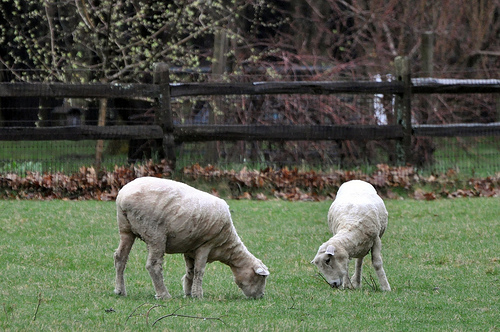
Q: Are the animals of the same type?
A: Yes, all the animals are sheep.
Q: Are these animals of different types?
A: No, all the animals are sheep.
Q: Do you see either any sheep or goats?
A: Yes, there is a sheep.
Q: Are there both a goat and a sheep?
A: No, there is a sheep but no goats.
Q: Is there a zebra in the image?
A: No, there are no zebras.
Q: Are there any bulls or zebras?
A: No, there are no zebras or bulls.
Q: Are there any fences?
A: Yes, there is a fence.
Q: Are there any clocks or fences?
A: Yes, there is a fence.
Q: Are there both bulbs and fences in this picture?
A: No, there is a fence but no light bulbs.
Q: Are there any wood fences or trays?
A: Yes, there is a wood fence.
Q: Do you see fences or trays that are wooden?
A: Yes, the fence is wooden.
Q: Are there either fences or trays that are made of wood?
A: Yes, the fence is made of wood.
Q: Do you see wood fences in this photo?
A: Yes, there is a wood fence.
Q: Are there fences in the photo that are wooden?
A: Yes, there is a fence that is wooden.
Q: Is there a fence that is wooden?
A: Yes, there is a fence that is wooden.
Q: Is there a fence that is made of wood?
A: Yes, there is a fence that is made of wood.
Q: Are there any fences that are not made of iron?
A: Yes, there is a fence that is made of wood.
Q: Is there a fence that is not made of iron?
A: Yes, there is a fence that is made of wood.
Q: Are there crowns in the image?
A: No, there are no crowns.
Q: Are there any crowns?
A: No, there are no crowns.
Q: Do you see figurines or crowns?
A: No, there are no crowns or figurines.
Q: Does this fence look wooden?
A: Yes, the fence is wooden.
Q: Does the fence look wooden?
A: Yes, the fence is wooden.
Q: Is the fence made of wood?
A: Yes, the fence is made of wood.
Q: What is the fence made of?
A: The fence is made of wood.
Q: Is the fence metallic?
A: No, the fence is wooden.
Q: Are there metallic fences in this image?
A: No, there is a fence but it is wooden.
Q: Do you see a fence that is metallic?
A: No, there is a fence but it is wooden.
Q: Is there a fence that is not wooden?
A: No, there is a fence but it is wooden.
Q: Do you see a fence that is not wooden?
A: No, there is a fence but it is wooden.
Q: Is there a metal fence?
A: No, there is a fence but it is made of wood.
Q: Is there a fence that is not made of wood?
A: No, there is a fence but it is made of wood.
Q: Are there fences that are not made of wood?
A: No, there is a fence but it is made of wood.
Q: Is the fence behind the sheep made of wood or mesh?
A: The fence is made of wood.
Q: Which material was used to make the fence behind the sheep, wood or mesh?
A: The fence is made of wood.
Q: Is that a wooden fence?
A: Yes, that is a wooden fence.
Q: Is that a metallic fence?
A: No, that is a wooden fence.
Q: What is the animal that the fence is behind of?
A: The animal is a sheep.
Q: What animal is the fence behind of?
A: The fence is behind the sheep.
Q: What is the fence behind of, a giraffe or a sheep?
A: The fence is behind a sheep.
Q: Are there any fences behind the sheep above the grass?
A: Yes, there is a fence behind the sheep.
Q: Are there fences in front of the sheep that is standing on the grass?
A: No, the fence is behind the sheep.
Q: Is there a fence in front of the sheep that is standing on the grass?
A: No, the fence is behind the sheep.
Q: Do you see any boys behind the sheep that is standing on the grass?
A: No, there is a fence behind the sheep.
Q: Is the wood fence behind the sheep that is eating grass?
A: Yes, the fence is behind the sheep.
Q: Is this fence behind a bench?
A: No, the fence is behind the sheep.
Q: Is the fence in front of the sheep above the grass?
A: No, the fence is behind the sheep.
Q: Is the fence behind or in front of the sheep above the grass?
A: The fence is behind the sheep.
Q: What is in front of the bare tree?
A: The fence is in front of the tree.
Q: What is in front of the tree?
A: The fence is in front of the tree.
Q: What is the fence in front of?
A: The fence is in front of the tree.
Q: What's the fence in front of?
A: The fence is in front of the tree.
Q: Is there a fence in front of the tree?
A: Yes, there is a fence in front of the tree.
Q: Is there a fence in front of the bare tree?
A: Yes, there is a fence in front of the tree.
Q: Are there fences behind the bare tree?
A: No, the fence is in front of the tree.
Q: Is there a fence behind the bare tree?
A: No, the fence is in front of the tree.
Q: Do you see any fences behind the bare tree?
A: No, the fence is in front of the tree.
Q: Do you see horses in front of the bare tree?
A: No, there is a fence in front of the tree.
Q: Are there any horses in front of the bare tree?
A: No, there is a fence in front of the tree.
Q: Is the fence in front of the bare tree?
A: Yes, the fence is in front of the tree.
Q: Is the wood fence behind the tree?
A: No, the fence is in front of the tree.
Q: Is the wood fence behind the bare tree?
A: No, the fence is in front of the tree.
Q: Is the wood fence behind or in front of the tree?
A: The fence is in front of the tree.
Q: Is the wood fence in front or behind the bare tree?
A: The fence is in front of the tree.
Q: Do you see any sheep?
A: Yes, there is a sheep.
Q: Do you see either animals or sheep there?
A: Yes, there is a sheep.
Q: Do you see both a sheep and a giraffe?
A: No, there is a sheep but no giraffes.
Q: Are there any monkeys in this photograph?
A: No, there are no monkeys.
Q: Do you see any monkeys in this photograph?
A: No, there are no monkeys.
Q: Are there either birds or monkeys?
A: No, there are no monkeys or birds.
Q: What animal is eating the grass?
A: The sheep is eating the grass.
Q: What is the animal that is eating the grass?
A: The animal is a sheep.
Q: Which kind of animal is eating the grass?
A: The animal is a sheep.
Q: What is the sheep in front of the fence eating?
A: The sheep is eating grass.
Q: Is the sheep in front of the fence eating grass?
A: Yes, the sheep is eating grass.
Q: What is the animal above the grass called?
A: The animal is a sheep.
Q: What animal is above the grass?
A: The animal is a sheep.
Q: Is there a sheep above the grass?
A: Yes, there is a sheep above the grass.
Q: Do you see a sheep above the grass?
A: Yes, there is a sheep above the grass.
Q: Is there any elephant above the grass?
A: No, there is a sheep above the grass.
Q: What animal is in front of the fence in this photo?
A: The sheep is in front of the fence.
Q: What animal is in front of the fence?
A: The sheep is in front of the fence.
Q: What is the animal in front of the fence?
A: The animal is a sheep.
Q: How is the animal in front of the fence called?
A: The animal is a sheep.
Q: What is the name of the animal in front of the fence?
A: The animal is a sheep.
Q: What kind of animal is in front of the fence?
A: The animal is a sheep.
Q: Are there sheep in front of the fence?
A: Yes, there is a sheep in front of the fence.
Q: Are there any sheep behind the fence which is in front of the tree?
A: No, the sheep is in front of the fence.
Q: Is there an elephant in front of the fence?
A: No, there is a sheep in front of the fence.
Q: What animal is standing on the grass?
A: The sheep is standing on the grass.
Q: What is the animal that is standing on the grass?
A: The animal is a sheep.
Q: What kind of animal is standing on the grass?
A: The animal is a sheep.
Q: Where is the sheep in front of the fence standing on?
A: The sheep is standing on the grass.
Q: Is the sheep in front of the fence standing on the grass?
A: Yes, the sheep is standing on the grass.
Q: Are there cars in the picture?
A: No, there are no cars.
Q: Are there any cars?
A: No, there are no cars.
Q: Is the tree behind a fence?
A: Yes, the tree is behind a fence.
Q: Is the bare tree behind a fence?
A: Yes, the tree is behind a fence.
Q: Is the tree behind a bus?
A: No, the tree is behind a fence.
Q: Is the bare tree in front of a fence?
A: No, the tree is behind a fence.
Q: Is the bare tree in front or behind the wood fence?
A: The tree is behind the fence.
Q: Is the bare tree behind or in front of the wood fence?
A: The tree is behind the fence.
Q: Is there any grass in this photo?
A: Yes, there is grass.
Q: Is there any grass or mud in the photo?
A: Yes, there is grass.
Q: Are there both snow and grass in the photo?
A: No, there is grass but no snow.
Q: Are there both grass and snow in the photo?
A: No, there is grass but no snow.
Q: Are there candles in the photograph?
A: No, there are no candles.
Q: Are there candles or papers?
A: No, there are no candles or papers.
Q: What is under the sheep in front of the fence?
A: The grass is under the sheep.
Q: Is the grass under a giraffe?
A: No, the grass is under the sheep.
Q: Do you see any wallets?
A: No, there are no wallets.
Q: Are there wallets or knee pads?
A: No, there are no wallets or knee pads.